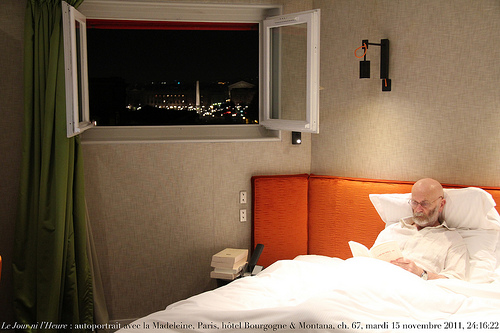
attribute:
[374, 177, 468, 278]
man — reading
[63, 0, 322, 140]
window — open, white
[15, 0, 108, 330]
curtain — green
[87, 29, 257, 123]
outside — dark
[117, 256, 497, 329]
bed coverings — white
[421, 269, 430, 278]
watch — black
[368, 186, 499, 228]
pillow — white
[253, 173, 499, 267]
back of bed — orange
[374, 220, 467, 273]
shirt — white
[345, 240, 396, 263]
book — white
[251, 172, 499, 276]
headboard — orange